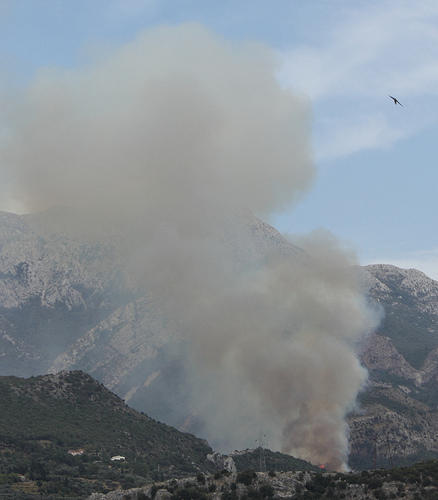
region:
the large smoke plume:
[0, 24, 386, 474]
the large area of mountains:
[0, 193, 436, 498]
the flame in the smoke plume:
[319, 463, 326, 468]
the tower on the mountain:
[253, 428, 269, 473]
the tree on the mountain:
[267, 468, 275, 479]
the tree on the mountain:
[235, 467, 256, 484]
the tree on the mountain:
[219, 468, 232, 477]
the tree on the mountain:
[213, 471, 223, 481]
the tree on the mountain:
[195, 472, 205, 484]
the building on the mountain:
[66, 447, 85, 457]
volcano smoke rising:
[10, 22, 392, 475]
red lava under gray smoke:
[293, 438, 354, 476]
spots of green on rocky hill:
[87, 462, 435, 499]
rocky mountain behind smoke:
[0, 195, 436, 469]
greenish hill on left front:
[0, 365, 327, 498]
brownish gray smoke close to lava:
[235, 227, 387, 471]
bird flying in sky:
[387, 94, 406, 108]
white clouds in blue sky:
[0, 0, 437, 274]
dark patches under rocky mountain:
[2, 281, 133, 379]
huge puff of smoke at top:
[1, 29, 338, 284]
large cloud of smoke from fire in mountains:
[17, 65, 375, 487]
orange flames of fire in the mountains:
[302, 448, 341, 481]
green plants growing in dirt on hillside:
[31, 362, 188, 494]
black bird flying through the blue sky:
[362, 76, 427, 167]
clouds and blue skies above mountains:
[368, 241, 435, 292]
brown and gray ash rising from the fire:
[236, 293, 354, 477]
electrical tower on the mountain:
[238, 412, 279, 482]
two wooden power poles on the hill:
[361, 426, 403, 482]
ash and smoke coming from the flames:
[281, 422, 354, 485]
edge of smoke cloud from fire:
[343, 334, 386, 487]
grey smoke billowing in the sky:
[1, 121, 384, 473]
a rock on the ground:
[110, 452, 127, 461]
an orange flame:
[319, 457, 327, 473]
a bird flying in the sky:
[387, 91, 404, 109]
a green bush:
[234, 466, 264, 484]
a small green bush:
[304, 478, 326, 491]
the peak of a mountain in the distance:
[359, 263, 433, 295]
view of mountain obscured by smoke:
[1, 190, 341, 404]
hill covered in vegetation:
[3, 364, 213, 467]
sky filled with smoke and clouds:
[1, 3, 433, 282]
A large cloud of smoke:
[8, 14, 399, 471]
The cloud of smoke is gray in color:
[3, 14, 385, 475]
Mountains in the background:
[1, 178, 434, 463]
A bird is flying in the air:
[378, 81, 413, 114]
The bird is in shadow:
[379, 85, 407, 112]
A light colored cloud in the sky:
[274, 1, 435, 180]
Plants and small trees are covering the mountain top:
[2, 365, 339, 483]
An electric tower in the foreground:
[249, 419, 277, 472]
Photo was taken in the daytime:
[3, 0, 435, 498]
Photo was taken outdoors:
[2, 3, 433, 499]